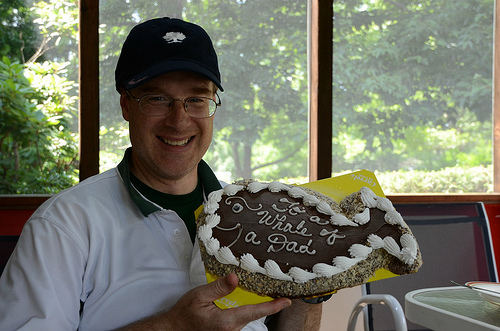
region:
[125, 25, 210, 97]
man has black hat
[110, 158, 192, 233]
man has black shirt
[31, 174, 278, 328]
man has white shirt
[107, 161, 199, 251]
man is wearing necklace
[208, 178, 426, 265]
white icing on cake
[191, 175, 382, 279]
brown icing on cake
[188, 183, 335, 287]
white writing on cake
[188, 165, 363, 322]
yellow plate under cake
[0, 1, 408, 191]
wood frame between windows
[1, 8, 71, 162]
green bushes outside windows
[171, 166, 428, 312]
A Cake in the shape of a whale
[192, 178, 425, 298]
Cake with almonds and chocolate and vanilla frosting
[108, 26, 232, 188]
Man with a huge smile on his face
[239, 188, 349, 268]
White Cursive Writing on the cake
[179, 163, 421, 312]
Yellow board the cake is on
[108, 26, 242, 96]
Baseball hat with a tree logo on it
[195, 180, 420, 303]
Crushed up almonds on the side of cake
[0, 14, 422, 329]
Man holding up his cake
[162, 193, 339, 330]
Hands holding the cake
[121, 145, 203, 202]
Wrinkles made in the man's neck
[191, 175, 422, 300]
Cake shaped like a whale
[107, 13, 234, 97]
The hat is black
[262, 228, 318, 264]
"Dad" written on the cake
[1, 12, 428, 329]
A man holding a cake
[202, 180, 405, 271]
Chocolate frosting on the cake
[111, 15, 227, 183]
The man is smiling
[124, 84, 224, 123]
A pair of eyeglasses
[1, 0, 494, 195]
Green trees outside the window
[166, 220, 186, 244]
A button on white shirt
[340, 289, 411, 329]
Top of a white chair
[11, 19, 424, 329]
a man holding a giant cookie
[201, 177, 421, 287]
big cookie with frosting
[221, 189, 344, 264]
white words written with frosting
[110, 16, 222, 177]
man wearing a black hat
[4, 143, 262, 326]
a white shirt with a green collar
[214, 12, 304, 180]
trees outside the window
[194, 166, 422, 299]
cookie shaped like a whale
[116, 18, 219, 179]
man wearing glasses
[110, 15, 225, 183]
the man is smiling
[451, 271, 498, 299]
a plate with a piece of silverware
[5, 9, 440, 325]
man holding a cake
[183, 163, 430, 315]
a cake is over a yellow board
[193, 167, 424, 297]
cake is shaped like a fish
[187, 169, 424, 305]
white decorations on cake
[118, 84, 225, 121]
glasses on face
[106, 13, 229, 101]
a blue cap on head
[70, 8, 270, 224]
a happy smiling man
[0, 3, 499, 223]
a window behind a man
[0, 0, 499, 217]
window has a brown frame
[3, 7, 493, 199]
trees can be seen through the window